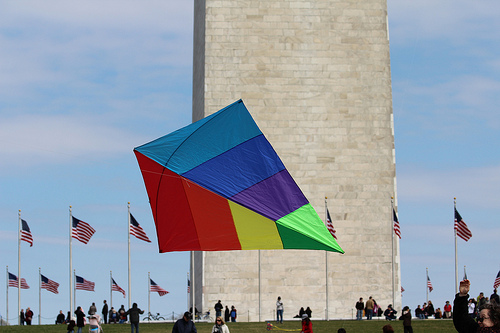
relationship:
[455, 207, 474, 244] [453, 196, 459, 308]
american flag on pole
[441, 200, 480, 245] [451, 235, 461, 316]
american flag on pole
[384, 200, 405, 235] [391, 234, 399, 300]
american flag on pole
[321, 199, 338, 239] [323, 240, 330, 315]
american flag on pole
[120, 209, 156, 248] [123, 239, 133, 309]
american flag on pole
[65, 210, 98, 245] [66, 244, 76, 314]
american flag on pole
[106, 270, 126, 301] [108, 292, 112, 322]
flag on pole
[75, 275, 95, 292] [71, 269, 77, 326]
american flags on pole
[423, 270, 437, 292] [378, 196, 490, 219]
flag on pole